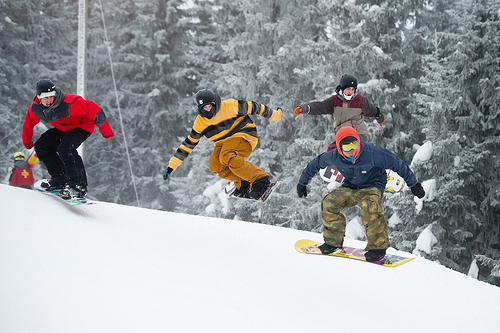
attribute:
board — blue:
[34, 175, 91, 212]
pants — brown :
[213, 156, 285, 183]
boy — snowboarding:
[291, 125, 428, 270]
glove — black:
[163, 166, 173, 178]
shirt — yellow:
[166, 97, 283, 172]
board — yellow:
[284, 232, 418, 267]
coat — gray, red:
[21, 98, 117, 147]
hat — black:
[315, 117, 377, 164]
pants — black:
[41, 130, 93, 188]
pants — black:
[43, 127, 98, 192]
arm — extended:
[381, 141, 423, 185]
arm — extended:
[291, 150, 328, 200]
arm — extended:
[362, 96, 386, 126]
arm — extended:
[288, 96, 329, 120]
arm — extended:
[160, 120, 200, 178]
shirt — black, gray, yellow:
[186, 113, 259, 138]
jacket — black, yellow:
[132, 77, 288, 164]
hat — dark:
[194, 87, 221, 119]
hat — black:
[333, 128, 363, 165]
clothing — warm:
[48, 107, 82, 182]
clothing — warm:
[213, 102, 243, 161]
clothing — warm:
[326, 97, 373, 122]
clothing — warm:
[340, 166, 390, 246]